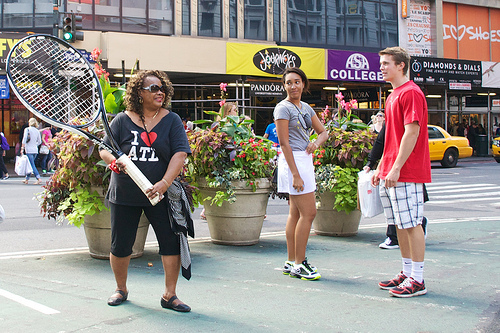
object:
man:
[369, 44, 433, 299]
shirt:
[376, 80, 431, 184]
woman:
[97, 68, 196, 314]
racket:
[4, 33, 164, 207]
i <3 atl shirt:
[99, 108, 191, 205]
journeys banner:
[225, 40, 325, 79]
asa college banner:
[327, 49, 386, 81]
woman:
[271, 66, 332, 281]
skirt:
[276, 150, 317, 197]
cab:
[426, 124, 473, 168]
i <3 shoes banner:
[442, 2, 500, 63]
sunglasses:
[137, 83, 168, 94]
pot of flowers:
[178, 82, 280, 209]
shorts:
[378, 178, 424, 230]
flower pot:
[74, 187, 149, 261]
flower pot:
[197, 178, 273, 246]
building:
[0, 0, 500, 170]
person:
[20, 118, 43, 185]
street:
[1, 158, 500, 253]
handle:
[114, 152, 164, 206]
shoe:
[288, 256, 322, 280]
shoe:
[387, 276, 427, 298]